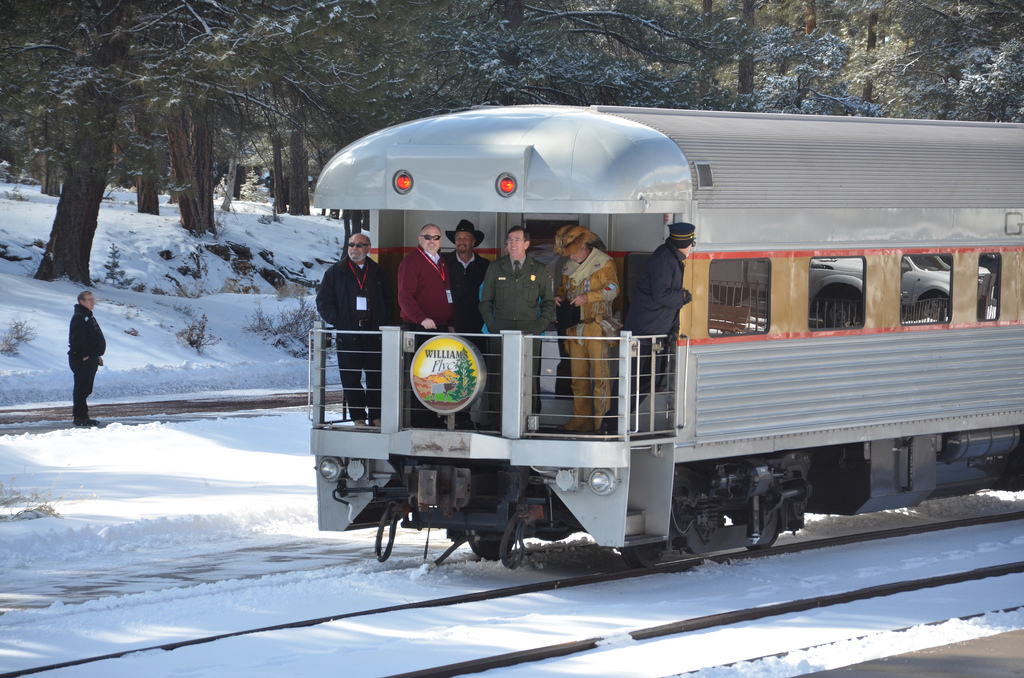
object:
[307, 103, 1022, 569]
train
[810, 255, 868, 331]
window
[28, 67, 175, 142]
green leaves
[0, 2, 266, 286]
tree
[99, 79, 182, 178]
leaves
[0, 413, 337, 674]
snow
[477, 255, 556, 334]
jacket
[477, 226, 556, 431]
badge